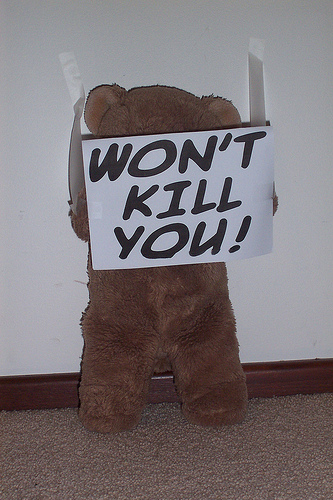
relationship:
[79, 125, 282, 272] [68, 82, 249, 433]
sign on stuffed bear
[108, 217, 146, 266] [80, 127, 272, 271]
letter on a sign